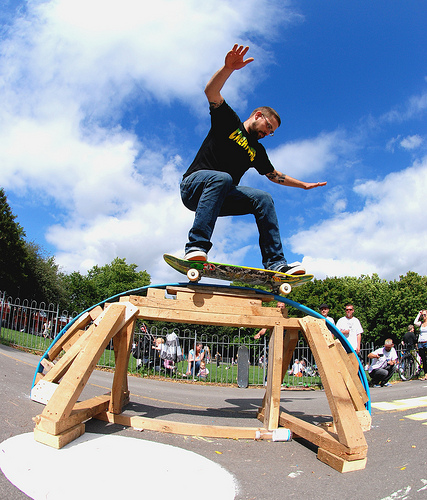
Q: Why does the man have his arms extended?
A: Balance.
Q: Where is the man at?
A: Skatepark.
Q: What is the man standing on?
A: Skate board.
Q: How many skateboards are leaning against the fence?
A: 1.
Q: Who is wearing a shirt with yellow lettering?
A: Skateboarding Man.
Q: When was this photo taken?
A: Daytime.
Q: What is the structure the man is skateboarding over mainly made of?
A: Wood.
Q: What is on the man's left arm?
A: Tattoo.